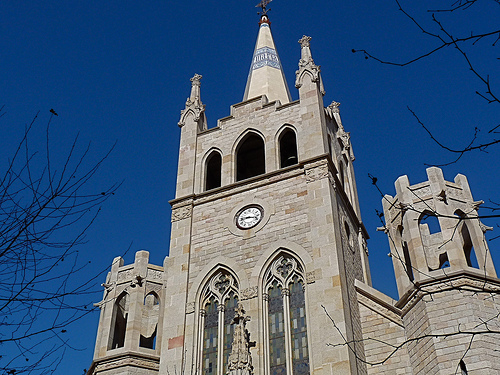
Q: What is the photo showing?
A: It is showing a church.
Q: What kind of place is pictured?
A: It is a church.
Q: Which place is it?
A: It is a church.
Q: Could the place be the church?
A: Yes, it is the church.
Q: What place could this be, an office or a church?
A: It is a church.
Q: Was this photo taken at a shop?
A: No, the picture was taken in a church.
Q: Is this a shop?
A: No, it is a church.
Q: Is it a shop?
A: No, it is a church.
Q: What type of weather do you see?
A: It is clear.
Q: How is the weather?
A: It is clear.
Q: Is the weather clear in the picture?
A: Yes, it is clear.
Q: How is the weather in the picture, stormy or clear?
A: It is clear.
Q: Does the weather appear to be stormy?
A: No, it is clear.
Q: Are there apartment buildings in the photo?
A: No, there are no apartment buildings.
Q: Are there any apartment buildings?
A: No, there are no apartment buildings.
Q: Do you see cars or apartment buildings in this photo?
A: No, there are no apartment buildings or cars.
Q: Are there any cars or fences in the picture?
A: No, there are no cars or fences.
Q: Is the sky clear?
A: Yes, the sky is clear.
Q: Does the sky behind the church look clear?
A: Yes, the sky is clear.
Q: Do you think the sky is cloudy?
A: No, the sky is clear.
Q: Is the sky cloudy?
A: No, the sky is clear.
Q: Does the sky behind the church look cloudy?
A: No, the sky is clear.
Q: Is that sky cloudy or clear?
A: The sky is clear.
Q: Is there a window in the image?
A: Yes, there are windows.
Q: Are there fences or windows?
A: Yes, there are windows.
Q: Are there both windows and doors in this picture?
A: No, there are windows but no doors.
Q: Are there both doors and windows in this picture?
A: No, there are windows but no doors.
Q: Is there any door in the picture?
A: No, there are no doors.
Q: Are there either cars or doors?
A: No, there are no doors or cars.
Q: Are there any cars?
A: No, there are no cars.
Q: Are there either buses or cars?
A: No, there are no cars or buses.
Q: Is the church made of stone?
A: Yes, the church is made of stone.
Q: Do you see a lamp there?
A: No, there are no lamps.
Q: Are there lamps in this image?
A: No, there are no lamps.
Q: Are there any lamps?
A: No, there are no lamps.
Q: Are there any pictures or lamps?
A: No, there are no lamps or pictures.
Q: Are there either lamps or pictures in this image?
A: No, there are no lamps or pictures.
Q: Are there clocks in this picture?
A: Yes, there is a clock.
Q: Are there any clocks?
A: Yes, there is a clock.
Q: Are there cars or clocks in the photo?
A: Yes, there is a clock.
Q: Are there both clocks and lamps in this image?
A: No, there is a clock but no lamps.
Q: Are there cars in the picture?
A: No, there are no cars.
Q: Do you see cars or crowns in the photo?
A: No, there are no cars or crowns.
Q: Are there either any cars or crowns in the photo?
A: No, there are no cars or crowns.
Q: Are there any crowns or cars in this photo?
A: No, there are no cars or crowns.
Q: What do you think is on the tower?
A: The clock is on the tower.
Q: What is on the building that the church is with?
A: The clock is on the tower.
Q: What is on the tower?
A: The clock is on the tower.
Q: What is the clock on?
A: The clock is on the tower.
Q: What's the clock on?
A: The clock is on the tower.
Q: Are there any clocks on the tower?
A: Yes, there is a clock on the tower.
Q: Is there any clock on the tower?
A: Yes, there is a clock on the tower.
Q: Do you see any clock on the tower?
A: Yes, there is a clock on the tower.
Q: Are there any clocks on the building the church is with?
A: Yes, there is a clock on the tower.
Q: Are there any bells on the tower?
A: No, there is a clock on the tower.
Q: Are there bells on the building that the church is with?
A: No, there is a clock on the tower.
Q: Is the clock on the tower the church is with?
A: Yes, the clock is on the tower.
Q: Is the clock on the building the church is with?
A: Yes, the clock is on the tower.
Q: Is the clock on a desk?
A: No, the clock is on the tower.